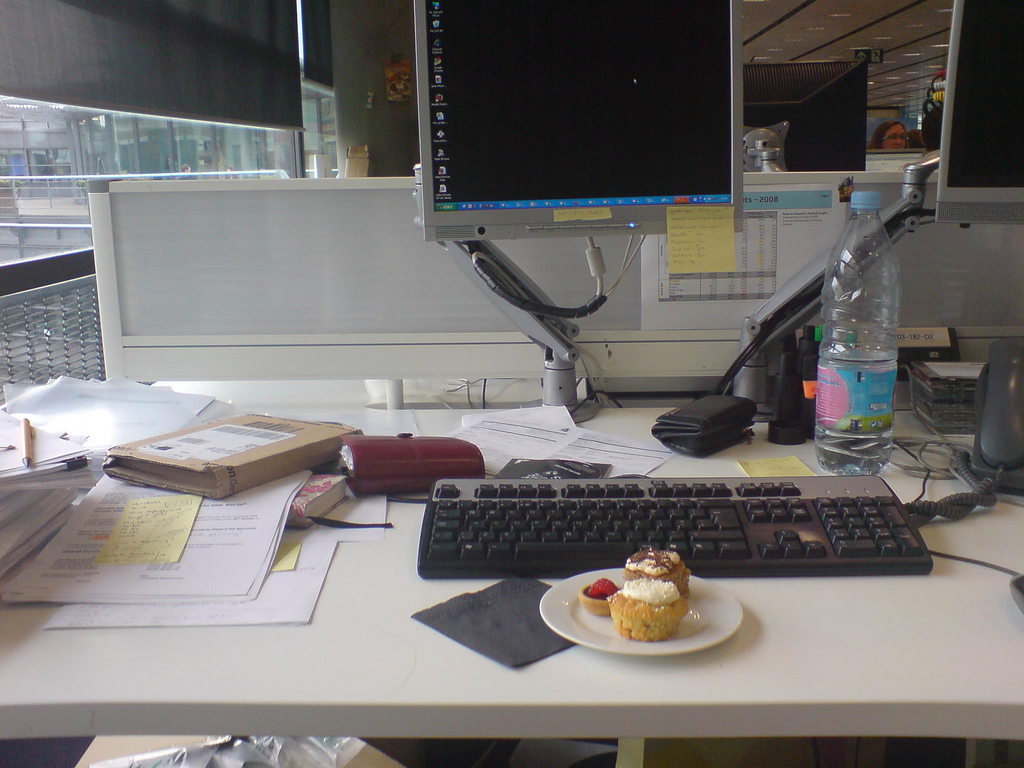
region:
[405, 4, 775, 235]
a silver computer monitor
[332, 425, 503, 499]
a red wallet on a desk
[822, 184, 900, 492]
a clear water bottle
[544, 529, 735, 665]
a white plate on a desk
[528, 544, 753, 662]
a plate with three cupcakes on it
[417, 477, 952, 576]
a black and silver computer keyboard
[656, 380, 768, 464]
a black wallet on a desk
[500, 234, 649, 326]
electrical cords on a computer monitor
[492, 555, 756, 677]
a plate on a desk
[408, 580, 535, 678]
a black napkin on a desk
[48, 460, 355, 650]
a bunch of papers on a desk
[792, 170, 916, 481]
a water bottle on a desk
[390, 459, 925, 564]
a black keyboard on a desk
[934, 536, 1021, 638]
a wire on a desk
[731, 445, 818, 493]
a yellow sticky note on a desk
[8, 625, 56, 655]
a shadow on a desk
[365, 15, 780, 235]
a grey computer moniter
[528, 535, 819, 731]
a nice plate on table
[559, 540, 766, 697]
food in the plate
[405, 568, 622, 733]
a paper in the table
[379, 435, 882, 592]
a key board in the table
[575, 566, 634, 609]
red pice in the food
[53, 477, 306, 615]
a paper near key board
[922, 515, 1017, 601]
wire of the key board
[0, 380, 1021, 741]
a white office desk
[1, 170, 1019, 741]
partition dividing white table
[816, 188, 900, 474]
tall water bottle with a blue top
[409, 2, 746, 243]
a computer monitor displaying small icons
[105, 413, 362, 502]
cardboard package with a label on it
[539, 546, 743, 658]
plate with pastries on it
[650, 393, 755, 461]
black wallet that appears full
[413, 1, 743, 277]
yellow sticky note stuck to bottom of monitor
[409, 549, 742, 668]
dark grey paper napkin partially beneath plate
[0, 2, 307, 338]
long row of windows set in a dark wall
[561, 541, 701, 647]
cupcakes on the plate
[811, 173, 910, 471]
water bottle on the desk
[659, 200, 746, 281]
post it on the monitor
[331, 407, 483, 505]
red book on the desk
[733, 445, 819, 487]
post it on the desk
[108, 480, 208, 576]
post it on the desk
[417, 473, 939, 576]
keyboard on the desk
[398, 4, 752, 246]
monitor on the desk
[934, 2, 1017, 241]
monitor on the desk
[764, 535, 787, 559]
A key on a keyboard.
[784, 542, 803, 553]
A key on a keyboard.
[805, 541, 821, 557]
A key on a keyboard.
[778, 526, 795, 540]
A key on a keyboard.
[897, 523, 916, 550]
A key on a keyboard.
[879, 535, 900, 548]
A key on a keyboard.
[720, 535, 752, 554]
A key on a keyboard.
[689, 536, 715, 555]
A key on a keyboard.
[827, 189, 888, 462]
clear plastic water bottle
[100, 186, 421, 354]
back wall of the cubicle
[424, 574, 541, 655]
black napkin on desk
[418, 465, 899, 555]
gray keyboard on computer desk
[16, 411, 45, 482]
a pen on pile of paper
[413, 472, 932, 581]
a black and silver keyboard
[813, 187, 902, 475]
a clear water bottle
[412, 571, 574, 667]
a black paper napkin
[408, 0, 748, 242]
a flat screen computer monitor